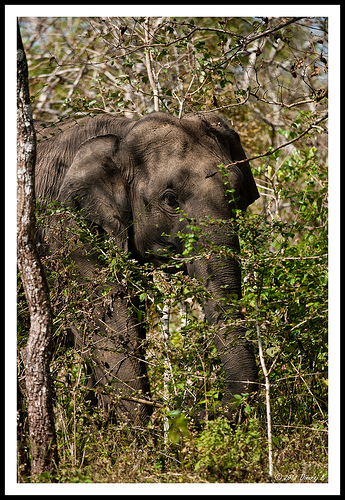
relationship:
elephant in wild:
[44, 101, 277, 459] [31, 32, 337, 478]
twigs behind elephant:
[222, 45, 280, 83] [44, 101, 277, 459]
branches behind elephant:
[50, 40, 100, 83] [44, 101, 277, 459]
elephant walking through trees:
[44, 101, 277, 459] [215, 40, 312, 121]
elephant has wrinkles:
[44, 101, 277, 459] [47, 155, 65, 171]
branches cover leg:
[50, 40, 100, 83] [72, 318, 163, 432]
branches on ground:
[50, 40, 100, 83] [163, 436, 275, 485]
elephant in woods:
[44, 101, 277, 459] [188, 43, 255, 85]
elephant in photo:
[44, 101, 277, 459] [31, 32, 337, 478]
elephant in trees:
[44, 101, 277, 459] [215, 40, 312, 121]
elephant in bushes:
[44, 101, 277, 459] [176, 417, 270, 464]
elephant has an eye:
[44, 101, 277, 459] [156, 191, 181, 205]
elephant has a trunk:
[44, 101, 277, 459] [200, 267, 262, 418]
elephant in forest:
[44, 101, 277, 459] [41, 69, 136, 112]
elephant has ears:
[44, 101, 277, 459] [77, 140, 130, 211]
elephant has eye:
[44, 101, 277, 459] [156, 191, 181, 205]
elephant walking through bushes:
[44, 101, 277, 459] [176, 417, 270, 464]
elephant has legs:
[44, 101, 277, 459] [51, 292, 177, 452]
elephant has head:
[44, 101, 277, 459] [91, 126, 242, 229]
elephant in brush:
[44, 101, 277, 459] [276, 312, 323, 462]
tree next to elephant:
[11, 80, 38, 188] [44, 101, 277, 459]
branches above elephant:
[50, 40, 100, 83] [44, 101, 277, 459]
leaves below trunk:
[187, 54, 229, 82] [200, 267, 262, 418]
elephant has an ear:
[44, 101, 277, 459] [213, 121, 258, 174]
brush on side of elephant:
[276, 312, 323, 462] [44, 101, 277, 459]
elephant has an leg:
[44, 101, 277, 459] [72, 318, 163, 432]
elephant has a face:
[44, 101, 277, 459] [141, 171, 247, 241]